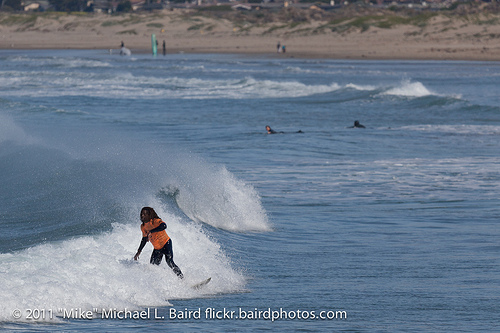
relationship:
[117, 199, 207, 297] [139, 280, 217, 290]
man on surfboard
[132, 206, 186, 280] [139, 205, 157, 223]
man with dreadlocks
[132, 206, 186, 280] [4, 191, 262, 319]
man rides wave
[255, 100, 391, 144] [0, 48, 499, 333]
people paddle out to ocean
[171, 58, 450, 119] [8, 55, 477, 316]
waves in ocean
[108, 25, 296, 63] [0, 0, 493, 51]
people on beach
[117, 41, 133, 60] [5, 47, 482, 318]
rock in water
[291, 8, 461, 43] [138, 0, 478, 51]
grass on sandy hill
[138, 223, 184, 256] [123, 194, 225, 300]
orange shirt on person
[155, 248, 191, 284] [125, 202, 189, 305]
black pants on surfer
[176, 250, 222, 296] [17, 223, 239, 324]
surf board peeking out of wave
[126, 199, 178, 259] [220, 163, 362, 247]
head in water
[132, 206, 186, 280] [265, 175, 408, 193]
man surfing water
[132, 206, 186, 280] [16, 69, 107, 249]
man surfing ocean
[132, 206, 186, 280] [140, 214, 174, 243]
man wearing top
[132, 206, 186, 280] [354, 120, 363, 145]
man wearing wetsuit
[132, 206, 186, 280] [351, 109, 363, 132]
man wearing wetsuit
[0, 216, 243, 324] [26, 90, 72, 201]
waves in ocean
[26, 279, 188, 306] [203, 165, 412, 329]
waves in ocean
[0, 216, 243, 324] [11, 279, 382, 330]
waves in ocean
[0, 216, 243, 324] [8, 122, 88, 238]
waves in ocean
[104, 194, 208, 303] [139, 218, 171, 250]
lady wearing orange shirt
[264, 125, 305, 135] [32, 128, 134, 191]
people swimming water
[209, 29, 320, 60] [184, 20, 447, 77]
people on beach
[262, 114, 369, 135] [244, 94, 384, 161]
people in water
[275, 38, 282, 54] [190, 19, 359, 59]
people on beach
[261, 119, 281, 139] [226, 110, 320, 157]
head in water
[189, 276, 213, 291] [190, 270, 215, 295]
surf board has tip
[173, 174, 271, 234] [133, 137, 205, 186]
wave has sprinkles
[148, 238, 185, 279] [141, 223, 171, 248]
pants under top